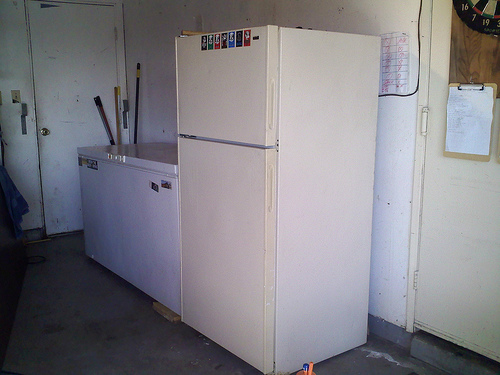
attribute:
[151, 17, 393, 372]
fridge — white